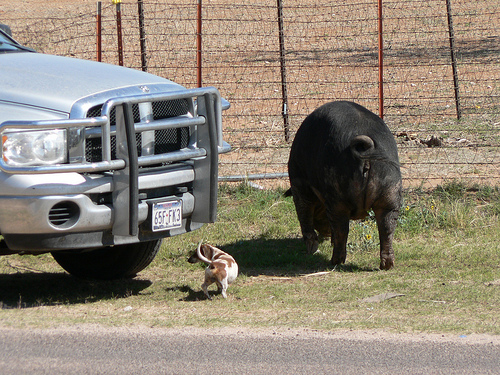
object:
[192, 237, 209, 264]
tail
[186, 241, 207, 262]
face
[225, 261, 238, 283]
white spots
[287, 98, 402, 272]
black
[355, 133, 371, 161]
small tail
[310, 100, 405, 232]
back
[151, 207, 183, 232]
license plate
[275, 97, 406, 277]
pig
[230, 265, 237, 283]
white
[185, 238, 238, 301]
dog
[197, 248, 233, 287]
brown spots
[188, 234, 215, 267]
tail up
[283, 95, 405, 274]
an animal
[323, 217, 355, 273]
leg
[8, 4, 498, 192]
fence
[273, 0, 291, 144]
post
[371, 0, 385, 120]
post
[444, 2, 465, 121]
post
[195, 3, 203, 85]
post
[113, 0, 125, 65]
post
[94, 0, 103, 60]
post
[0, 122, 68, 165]
headlight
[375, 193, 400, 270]
leg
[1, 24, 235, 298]
car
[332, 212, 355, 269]
legs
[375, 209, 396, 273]
legs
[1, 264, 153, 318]
shadow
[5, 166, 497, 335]
grass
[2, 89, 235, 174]
grill